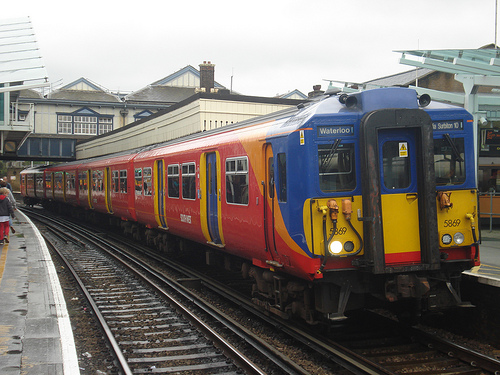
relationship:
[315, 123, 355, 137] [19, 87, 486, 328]
sign on front of train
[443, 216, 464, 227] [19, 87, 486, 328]
train number on front of train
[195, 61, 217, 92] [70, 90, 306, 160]
chimney on top of building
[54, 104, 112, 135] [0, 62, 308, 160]
window attached to building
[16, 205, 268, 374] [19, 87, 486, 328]
tracks under train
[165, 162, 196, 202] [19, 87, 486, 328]
windows attached to train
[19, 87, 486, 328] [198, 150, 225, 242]
train has door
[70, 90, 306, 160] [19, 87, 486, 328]
building behind train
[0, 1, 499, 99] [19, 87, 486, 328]
sky above train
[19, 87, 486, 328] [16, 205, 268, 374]
train on top of tracks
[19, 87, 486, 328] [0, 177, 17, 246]
train next to people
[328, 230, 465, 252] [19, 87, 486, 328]
headlights attached to train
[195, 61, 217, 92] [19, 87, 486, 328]
chimney behind train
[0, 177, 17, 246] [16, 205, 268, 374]
people next to tracks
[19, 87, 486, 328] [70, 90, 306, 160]
train in front of building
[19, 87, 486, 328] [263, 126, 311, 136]
train has red stripe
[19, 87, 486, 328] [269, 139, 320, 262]
train has blue stripe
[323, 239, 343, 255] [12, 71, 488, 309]
headlight on train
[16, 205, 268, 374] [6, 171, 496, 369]
tracks in station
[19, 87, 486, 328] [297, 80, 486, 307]
train has front